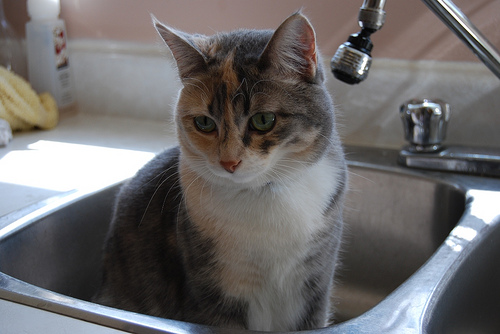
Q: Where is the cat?
A: In a sink.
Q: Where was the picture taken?
A: In a kitchen.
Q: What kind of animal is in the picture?
A: A cat.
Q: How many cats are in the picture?
A: 1.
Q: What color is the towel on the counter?
A: Yellow.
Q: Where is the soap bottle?
A: On the counter.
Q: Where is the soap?
A: On the counter.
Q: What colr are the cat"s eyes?
A: Green.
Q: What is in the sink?
A: Cat.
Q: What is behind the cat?
A: Faucet.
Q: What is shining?
A: The glare.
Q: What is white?
A: The cat's neck.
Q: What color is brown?
A: The cat's head.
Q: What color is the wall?
A: Pink.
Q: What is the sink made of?
A: Steel.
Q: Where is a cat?
A: In a sink.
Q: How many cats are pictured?
A: One.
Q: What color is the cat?
A: Gray and white.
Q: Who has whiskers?
A: The cat.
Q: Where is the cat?
A: In a sink.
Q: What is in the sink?
A: A cat.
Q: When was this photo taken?
A: Daytime.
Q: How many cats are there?
A: One.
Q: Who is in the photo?
A: Nobody.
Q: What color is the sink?
A: Silver.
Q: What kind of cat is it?
A: Calico.